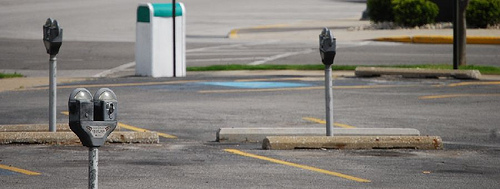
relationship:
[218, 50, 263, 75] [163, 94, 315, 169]
grass on road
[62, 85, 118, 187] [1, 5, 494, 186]
parking meter in a lot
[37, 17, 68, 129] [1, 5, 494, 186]
parking meter in a lot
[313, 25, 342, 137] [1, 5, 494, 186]
parking meter in a lot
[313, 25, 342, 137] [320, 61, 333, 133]
parking meter on a post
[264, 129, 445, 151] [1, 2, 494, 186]
cement slab on road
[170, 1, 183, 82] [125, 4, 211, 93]
pole in front of can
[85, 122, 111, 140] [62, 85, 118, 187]
sign on parking meter